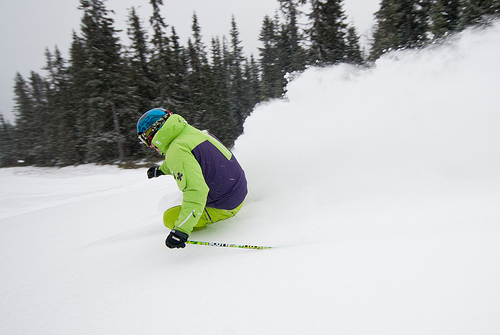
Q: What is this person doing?
A: Skiing.